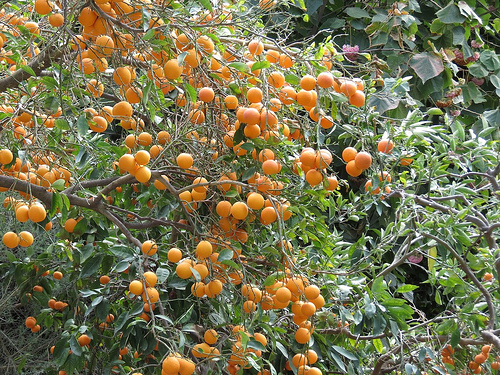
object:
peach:
[243, 107, 260, 124]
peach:
[134, 149, 150, 163]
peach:
[27, 204, 47, 223]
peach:
[231, 201, 248, 219]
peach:
[167, 247, 182, 263]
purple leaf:
[339, 42, 361, 62]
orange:
[210, 76, 281, 154]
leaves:
[340, 290, 395, 334]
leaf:
[403, 52, 443, 84]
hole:
[387, 252, 450, 329]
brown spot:
[55, 203, 61, 214]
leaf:
[46, 187, 62, 219]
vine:
[141, 122, 188, 207]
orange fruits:
[89, 12, 361, 210]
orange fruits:
[152, 243, 312, 373]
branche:
[4, 177, 120, 207]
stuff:
[56, 25, 391, 325]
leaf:
[343, 232, 372, 260]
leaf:
[390, 276, 419, 297]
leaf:
[384, 302, 416, 321]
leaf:
[330, 282, 361, 309]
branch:
[432, 153, 497, 188]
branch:
[389, 172, 498, 239]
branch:
[401, 212, 497, 336]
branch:
[356, 227, 426, 282]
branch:
[334, 187, 412, 236]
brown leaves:
[386, 3, 408, 18]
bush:
[0, 0, 500, 374]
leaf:
[184, 342, 226, 361]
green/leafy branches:
[385, 169, 499, 371]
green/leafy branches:
[0, 160, 269, 298]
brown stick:
[418, 230, 498, 344]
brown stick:
[1, 174, 177, 207]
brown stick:
[0, 42, 64, 91]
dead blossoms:
[433, 86, 468, 116]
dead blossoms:
[455, 47, 482, 64]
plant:
[355, 1, 497, 121]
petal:
[408, 248, 423, 265]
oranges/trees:
[1, 0, 499, 375]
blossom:
[338, 42, 360, 60]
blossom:
[450, 43, 477, 64]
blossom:
[453, 108, 464, 117]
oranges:
[3, 9, 327, 366]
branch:
[2, 214, 64, 369]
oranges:
[242, 119, 264, 144]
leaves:
[325, 216, 467, 343]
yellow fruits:
[0, 0, 412, 375]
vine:
[275, 320, 383, 343]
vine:
[300, 42, 357, 61]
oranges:
[177, 71, 330, 266]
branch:
[111, 138, 338, 229]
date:
[191, 360, 201, 371]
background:
[0, 0, 499, 375]